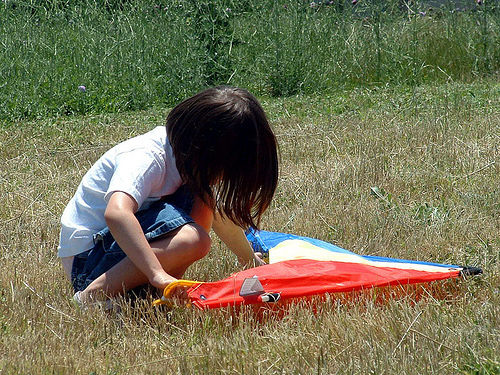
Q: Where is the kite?
A: On the ground.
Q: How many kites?
A: 1.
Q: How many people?
A: 1.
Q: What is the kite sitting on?
A: Grass.